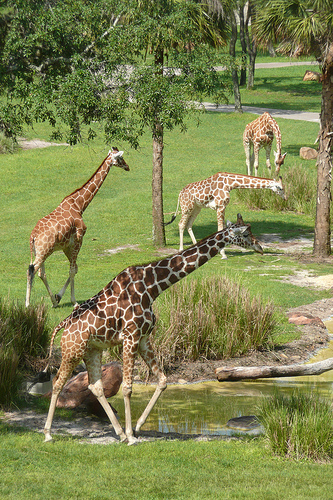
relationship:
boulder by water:
[50, 362, 125, 415] [93, 376, 332, 434]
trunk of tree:
[153, 130, 165, 247] [4, 2, 246, 247]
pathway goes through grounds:
[126, 90, 333, 124] [0, 42, 332, 490]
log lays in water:
[213, 358, 333, 383] [93, 376, 332, 434]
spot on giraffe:
[140, 269, 158, 285] [43, 214, 261, 446]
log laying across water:
[213, 358, 333, 383] [93, 376, 332, 434]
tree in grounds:
[4, 2, 246, 247] [0, 42, 332, 490]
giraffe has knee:
[43, 214, 261, 446] [119, 384, 133, 401]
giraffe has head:
[43, 214, 261, 446] [230, 210, 266, 256]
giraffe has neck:
[43, 214, 261, 446] [144, 227, 228, 300]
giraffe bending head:
[241, 110, 286, 176] [269, 152, 283, 174]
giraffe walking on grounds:
[23, 147, 131, 305] [0, 42, 332, 490]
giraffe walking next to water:
[43, 214, 261, 446] [93, 376, 332, 434]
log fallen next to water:
[213, 358, 333, 383] [93, 376, 332, 434]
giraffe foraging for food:
[241, 110, 286, 176] [254, 170, 315, 212]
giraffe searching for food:
[241, 110, 286, 176] [254, 170, 315, 212]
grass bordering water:
[270, 408, 332, 464] [93, 376, 332, 434]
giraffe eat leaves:
[241, 110, 286, 176] [131, 72, 188, 134]